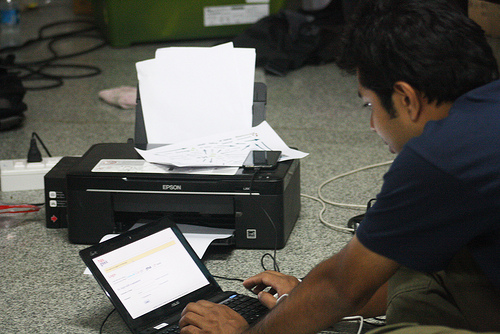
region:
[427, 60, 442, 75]
Man has dark hair.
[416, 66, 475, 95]
Man has short hair.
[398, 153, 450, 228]
Man wearing blue shirt.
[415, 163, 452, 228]
Man wearing t-shirt.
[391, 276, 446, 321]
Man wearing gray pants.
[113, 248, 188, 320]
Black laptop sitting on floor.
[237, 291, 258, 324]
Black buttons on laptop.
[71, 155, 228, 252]
Black printer sitting on floor.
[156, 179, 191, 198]
White writing on printer.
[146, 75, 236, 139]
White paper in printer.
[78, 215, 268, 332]
a small black laptop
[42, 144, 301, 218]
a black Epson printer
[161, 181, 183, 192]
the manufacturer name brand logo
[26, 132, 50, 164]
a black power chord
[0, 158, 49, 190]
a beige power strip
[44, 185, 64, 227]
the control panel of the printer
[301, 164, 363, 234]
a computer mouse and cable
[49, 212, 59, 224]
the printers power light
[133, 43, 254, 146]
a stack of printing paper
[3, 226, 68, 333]
a grey carpet on the floor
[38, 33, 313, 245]
a black Epson printer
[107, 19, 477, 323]
a man working at a laptop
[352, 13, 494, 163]
the head of a man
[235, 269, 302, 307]
the hand of a man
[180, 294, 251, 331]
the hand of a man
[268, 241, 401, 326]
the arm of a man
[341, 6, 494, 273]
a man wearing a blue shirt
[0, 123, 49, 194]
a white power strip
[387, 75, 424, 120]
the ear of a man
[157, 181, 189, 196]
white writing on a printer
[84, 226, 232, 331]
small open lap top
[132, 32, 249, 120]
white paper in a printer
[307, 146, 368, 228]
white wires on the ground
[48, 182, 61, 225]
buttons on a printer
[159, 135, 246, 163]
printed piece of white paper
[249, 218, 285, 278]
black wires on the ground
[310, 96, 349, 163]
grey carpeting on the ground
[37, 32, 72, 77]
black wires on the ground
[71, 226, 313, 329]
Laptop landed on the floor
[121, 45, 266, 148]
Paper inside the printer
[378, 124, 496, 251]
man wearing a blue shirt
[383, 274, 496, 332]
man wearing green pants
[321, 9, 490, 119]
man with black hair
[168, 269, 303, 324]
Man working on a laptop computer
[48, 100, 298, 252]
Epson printer on the floor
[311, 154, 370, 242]
computer cord on the floor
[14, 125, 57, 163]
Printer plugged into a surge protector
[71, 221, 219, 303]
Laptop screen with the power on